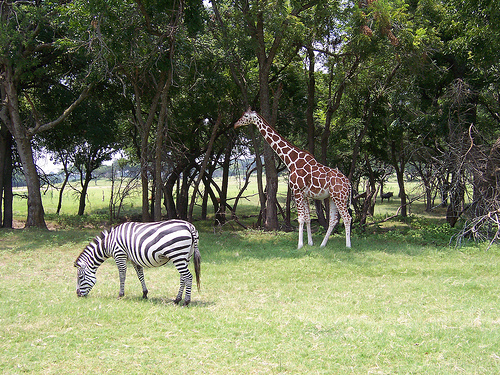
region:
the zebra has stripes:
[45, 153, 271, 358]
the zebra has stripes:
[47, 134, 214, 294]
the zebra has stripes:
[2, 54, 224, 368]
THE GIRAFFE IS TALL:
[231, 97, 366, 254]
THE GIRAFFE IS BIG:
[231, 100, 358, 257]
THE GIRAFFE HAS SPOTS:
[233, 103, 360, 263]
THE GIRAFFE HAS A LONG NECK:
[233, 110, 364, 252]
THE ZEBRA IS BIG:
[63, 210, 211, 318]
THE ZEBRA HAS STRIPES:
[70, 204, 204, 324]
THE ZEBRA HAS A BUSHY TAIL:
[187, 222, 208, 296]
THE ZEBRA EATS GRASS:
[56, 215, 211, 324]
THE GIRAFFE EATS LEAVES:
[228, 98, 363, 262]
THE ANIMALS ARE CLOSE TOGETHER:
[61, 101, 359, 327]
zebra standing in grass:
[59, 211, 211, 316]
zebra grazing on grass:
[55, 206, 212, 313]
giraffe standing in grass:
[227, 103, 361, 259]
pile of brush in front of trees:
[401, 111, 499, 249]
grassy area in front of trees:
[11, 220, 497, 371]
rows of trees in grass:
[1, 16, 499, 231]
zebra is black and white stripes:
[71, 206, 213, 320]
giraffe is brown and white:
[223, 106, 368, 261]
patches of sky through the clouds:
[11, 131, 268, 172]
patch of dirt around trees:
[5, 203, 96, 240]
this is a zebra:
[60, 210, 207, 309]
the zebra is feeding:
[57, 215, 207, 311]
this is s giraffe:
[242, 108, 351, 265]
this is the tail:
[191, 245, 203, 272]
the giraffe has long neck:
[230, 111, 302, 161]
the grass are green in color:
[307, 267, 412, 354]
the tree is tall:
[242, 31, 294, 90]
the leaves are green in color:
[109, 2, 144, 48]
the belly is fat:
[133, 245, 160, 265]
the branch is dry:
[434, 147, 491, 205]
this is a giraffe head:
[217, 83, 272, 140]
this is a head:
[66, 229, 100, 311]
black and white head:
[52, 252, 112, 305]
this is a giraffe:
[226, 101, 379, 271]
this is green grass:
[313, 310, 383, 370]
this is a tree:
[125, 67, 228, 228]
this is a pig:
[376, 187, 400, 207]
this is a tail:
[173, 208, 211, 302]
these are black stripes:
[113, 229, 163, 263]